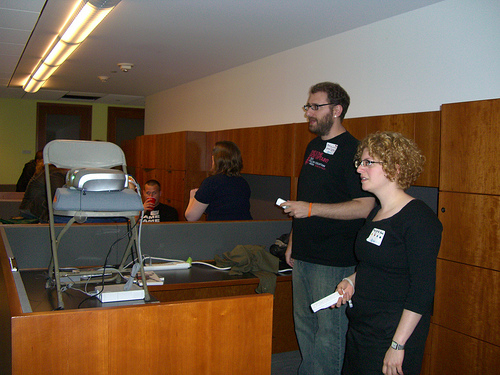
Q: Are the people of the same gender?
A: No, they are both male and female.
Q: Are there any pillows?
A: No, there are no pillows.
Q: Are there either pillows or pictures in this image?
A: No, there are no pillows or pictures.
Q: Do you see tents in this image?
A: No, there are no tents.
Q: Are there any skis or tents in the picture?
A: No, there are no tents or skis.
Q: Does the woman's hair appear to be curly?
A: Yes, the hair is curly.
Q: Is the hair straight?
A: No, the hair is curly.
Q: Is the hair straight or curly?
A: The hair is curly.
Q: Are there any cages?
A: No, there are no cages.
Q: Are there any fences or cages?
A: No, there are no cages or fences.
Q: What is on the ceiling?
A: The light fixture is on the ceiling.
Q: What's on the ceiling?
A: The light fixture is on the ceiling.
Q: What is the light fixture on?
A: The light fixture is on the ceiling.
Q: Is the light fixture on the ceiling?
A: Yes, the light fixture is on the ceiling.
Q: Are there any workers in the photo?
A: No, there are no workers.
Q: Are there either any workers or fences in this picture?
A: No, there are no workers or fences.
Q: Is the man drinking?
A: Yes, the man is drinking.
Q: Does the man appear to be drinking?
A: Yes, the man is drinking.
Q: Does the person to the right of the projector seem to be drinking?
A: Yes, the man is drinking.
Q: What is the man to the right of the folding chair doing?
A: The man is drinking.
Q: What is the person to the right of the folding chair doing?
A: The man is drinking.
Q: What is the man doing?
A: The man is drinking.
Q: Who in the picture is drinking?
A: The man is drinking.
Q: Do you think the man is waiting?
A: No, the man is drinking.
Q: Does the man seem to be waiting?
A: No, the man is drinking.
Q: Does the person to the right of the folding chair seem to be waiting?
A: No, the man is drinking.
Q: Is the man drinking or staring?
A: The man is drinking.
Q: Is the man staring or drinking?
A: The man is drinking.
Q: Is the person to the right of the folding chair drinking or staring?
A: The man is drinking.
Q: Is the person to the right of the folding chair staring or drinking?
A: The man is drinking.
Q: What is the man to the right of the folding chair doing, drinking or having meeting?
A: The man is drinking.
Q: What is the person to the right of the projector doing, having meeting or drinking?
A: The man is drinking.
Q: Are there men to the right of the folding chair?
A: Yes, there is a man to the right of the folding chair.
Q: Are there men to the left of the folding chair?
A: No, the man is to the right of the folding chair.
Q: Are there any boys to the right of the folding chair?
A: No, there is a man to the right of the folding chair.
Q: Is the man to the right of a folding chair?
A: Yes, the man is to the right of a folding chair.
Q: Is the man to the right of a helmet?
A: No, the man is to the right of a folding chair.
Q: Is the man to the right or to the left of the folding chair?
A: The man is to the right of the folding chair.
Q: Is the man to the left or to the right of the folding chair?
A: The man is to the right of the folding chair.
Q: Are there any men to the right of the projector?
A: Yes, there is a man to the right of the projector.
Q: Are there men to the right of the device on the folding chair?
A: Yes, there is a man to the right of the projector.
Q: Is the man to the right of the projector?
A: Yes, the man is to the right of the projector.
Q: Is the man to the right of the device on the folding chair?
A: Yes, the man is to the right of the projector.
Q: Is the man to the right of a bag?
A: No, the man is to the right of the projector.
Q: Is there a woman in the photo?
A: Yes, there is a woman.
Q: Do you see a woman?
A: Yes, there is a woman.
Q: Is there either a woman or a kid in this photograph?
A: Yes, there is a woman.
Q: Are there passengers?
A: No, there are no passengers.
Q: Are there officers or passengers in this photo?
A: No, there are no passengers or officers.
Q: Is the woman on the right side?
A: Yes, the woman is on the right of the image.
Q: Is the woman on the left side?
A: No, the woman is on the right of the image.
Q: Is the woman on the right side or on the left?
A: The woman is on the right of the image.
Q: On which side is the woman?
A: The woman is on the right of the image.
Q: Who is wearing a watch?
A: The woman is wearing a watch.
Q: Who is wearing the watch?
A: The woman is wearing a watch.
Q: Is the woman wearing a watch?
A: Yes, the woman is wearing a watch.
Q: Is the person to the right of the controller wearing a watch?
A: Yes, the woman is wearing a watch.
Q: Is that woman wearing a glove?
A: No, the woman is wearing a watch.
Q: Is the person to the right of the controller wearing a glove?
A: No, the woman is wearing a watch.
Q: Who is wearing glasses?
A: The woman is wearing glasses.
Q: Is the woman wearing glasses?
A: Yes, the woman is wearing glasses.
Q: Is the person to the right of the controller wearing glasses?
A: Yes, the woman is wearing glasses.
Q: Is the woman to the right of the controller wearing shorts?
A: No, the woman is wearing glasses.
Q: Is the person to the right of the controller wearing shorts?
A: No, the woman is wearing glasses.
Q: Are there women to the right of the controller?
A: Yes, there is a woman to the right of the controller.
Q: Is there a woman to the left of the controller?
A: No, the woman is to the right of the controller.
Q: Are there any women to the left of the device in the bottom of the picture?
A: No, the woman is to the right of the controller.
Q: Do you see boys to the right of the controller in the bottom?
A: No, there is a woman to the right of the controller.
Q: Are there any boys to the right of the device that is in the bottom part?
A: No, there is a woman to the right of the controller.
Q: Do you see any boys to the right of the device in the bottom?
A: No, there is a woman to the right of the controller.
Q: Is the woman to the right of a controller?
A: Yes, the woman is to the right of a controller.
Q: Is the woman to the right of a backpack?
A: No, the woman is to the right of a controller.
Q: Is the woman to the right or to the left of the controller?
A: The woman is to the right of the controller.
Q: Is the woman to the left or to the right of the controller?
A: The woman is to the right of the controller.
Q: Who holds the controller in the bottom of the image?
A: The woman holds the controller.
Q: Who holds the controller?
A: The woman holds the controller.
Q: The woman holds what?
A: The woman holds the controller.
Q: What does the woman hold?
A: The woman holds the controller.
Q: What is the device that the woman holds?
A: The device is a controller.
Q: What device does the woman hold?
A: The woman holds the controller.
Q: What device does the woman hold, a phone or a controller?
A: The woman holds a controller.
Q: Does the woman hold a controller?
A: Yes, the woman holds a controller.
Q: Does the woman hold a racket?
A: No, the woman holds a controller.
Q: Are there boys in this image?
A: No, there are no boys.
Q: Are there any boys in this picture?
A: No, there are no boys.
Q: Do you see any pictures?
A: No, there are no pictures.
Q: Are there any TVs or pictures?
A: No, there are no pictures or tvs.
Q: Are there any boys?
A: No, there are no boys.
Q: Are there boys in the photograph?
A: No, there are no boys.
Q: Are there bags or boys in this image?
A: No, there are no boys or bags.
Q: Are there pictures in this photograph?
A: No, there are no pictures.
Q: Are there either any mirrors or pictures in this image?
A: No, there are no pictures or mirrors.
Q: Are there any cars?
A: No, there are no cars.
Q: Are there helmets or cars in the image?
A: No, there are no cars or helmets.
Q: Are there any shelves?
A: No, there are no shelves.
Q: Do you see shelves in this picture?
A: No, there are no shelves.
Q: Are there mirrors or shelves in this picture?
A: No, there are no shelves or mirrors.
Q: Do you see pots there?
A: No, there are no pots.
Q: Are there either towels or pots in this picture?
A: No, there are no pots or towels.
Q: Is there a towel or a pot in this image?
A: No, there are no pots or towels.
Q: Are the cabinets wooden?
A: Yes, the cabinets are wooden.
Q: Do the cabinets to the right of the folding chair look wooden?
A: Yes, the cabinets are wooden.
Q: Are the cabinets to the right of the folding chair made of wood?
A: Yes, the cabinets are made of wood.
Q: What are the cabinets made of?
A: The cabinets are made of wood.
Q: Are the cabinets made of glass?
A: No, the cabinets are made of wood.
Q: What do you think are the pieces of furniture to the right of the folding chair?
A: The pieces of furniture are cabinets.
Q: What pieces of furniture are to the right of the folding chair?
A: The pieces of furniture are cabinets.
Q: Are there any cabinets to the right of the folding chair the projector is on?
A: Yes, there are cabinets to the right of the folding chair.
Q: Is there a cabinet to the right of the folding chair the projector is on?
A: Yes, there are cabinets to the right of the folding chair.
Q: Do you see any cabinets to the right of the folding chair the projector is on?
A: Yes, there are cabinets to the right of the folding chair.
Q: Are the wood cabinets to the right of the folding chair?
A: Yes, the cabinets are to the right of the folding chair.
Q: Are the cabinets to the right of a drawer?
A: No, the cabinets are to the right of the folding chair.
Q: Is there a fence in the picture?
A: No, there are no fences.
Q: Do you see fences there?
A: No, there are no fences.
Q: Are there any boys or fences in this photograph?
A: No, there are no fences or boys.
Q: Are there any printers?
A: No, there are no printers.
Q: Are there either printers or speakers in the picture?
A: No, there are no printers or speakers.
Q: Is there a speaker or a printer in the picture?
A: No, there are no printers or speakers.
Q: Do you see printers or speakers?
A: No, there are no printers or speakers.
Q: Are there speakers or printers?
A: No, there are no printers or speakers.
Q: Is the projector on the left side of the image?
A: Yes, the projector is on the left of the image.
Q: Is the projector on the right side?
A: No, the projector is on the left of the image.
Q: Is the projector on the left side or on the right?
A: The projector is on the left of the image.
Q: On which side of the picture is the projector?
A: The projector is on the left of the image.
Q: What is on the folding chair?
A: The projector is on the folding chair.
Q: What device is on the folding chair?
A: The device is a projector.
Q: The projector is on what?
A: The projector is on the folding chair.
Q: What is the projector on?
A: The projector is on the folding chair.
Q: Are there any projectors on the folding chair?
A: Yes, there is a projector on the folding chair.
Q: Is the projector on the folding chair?
A: Yes, the projector is on the folding chair.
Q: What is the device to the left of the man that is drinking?
A: The device is a projector.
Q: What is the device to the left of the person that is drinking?
A: The device is a projector.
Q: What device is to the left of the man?
A: The device is a projector.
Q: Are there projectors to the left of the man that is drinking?
A: Yes, there is a projector to the left of the man.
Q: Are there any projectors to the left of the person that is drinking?
A: Yes, there is a projector to the left of the man.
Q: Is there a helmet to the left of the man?
A: No, there is a projector to the left of the man.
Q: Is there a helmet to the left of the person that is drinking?
A: No, there is a projector to the left of the man.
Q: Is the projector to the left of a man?
A: Yes, the projector is to the left of a man.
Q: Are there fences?
A: No, there are no fences.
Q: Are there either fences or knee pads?
A: No, there are no fences or knee pads.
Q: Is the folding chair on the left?
A: Yes, the folding chair is on the left of the image.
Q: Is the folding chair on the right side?
A: No, the folding chair is on the left of the image.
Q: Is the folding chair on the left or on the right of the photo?
A: The folding chair is on the left of the image.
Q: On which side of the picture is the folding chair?
A: The folding chair is on the left of the image.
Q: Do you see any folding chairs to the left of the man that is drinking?
A: Yes, there is a folding chair to the left of the man.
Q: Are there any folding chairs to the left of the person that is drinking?
A: Yes, there is a folding chair to the left of the man.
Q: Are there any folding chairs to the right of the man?
A: No, the folding chair is to the left of the man.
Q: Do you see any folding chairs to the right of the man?
A: No, the folding chair is to the left of the man.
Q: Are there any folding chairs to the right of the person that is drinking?
A: No, the folding chair is to the left of the man.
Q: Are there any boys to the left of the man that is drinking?
A: No, there is a folding chair to the left of the man.